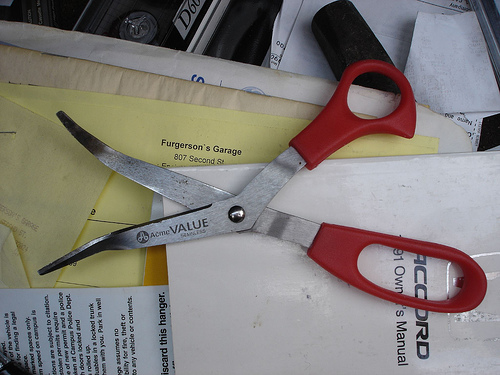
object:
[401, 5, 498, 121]
paper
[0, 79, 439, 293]
yellow paper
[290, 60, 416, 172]
handles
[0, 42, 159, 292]
paper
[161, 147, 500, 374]
paper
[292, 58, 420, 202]
microphone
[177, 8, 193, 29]
letter d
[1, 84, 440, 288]
receipt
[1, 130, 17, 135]
staple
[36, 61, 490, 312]
scissors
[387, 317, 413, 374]
word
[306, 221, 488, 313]
handle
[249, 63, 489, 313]
opening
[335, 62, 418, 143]
opening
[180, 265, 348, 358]
manual